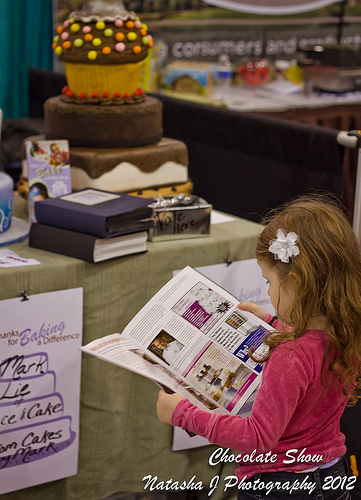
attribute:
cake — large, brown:
[28, 0, 214, 208]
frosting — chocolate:
[50, 5, 153, 60]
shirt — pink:
[168, 313, 356, 486]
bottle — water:
[217, 53, 230, 92]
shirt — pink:
[171, 326, 350, 467]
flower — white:
[263, 228, 302, 263]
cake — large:
[17, 0, 190, 208]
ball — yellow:
[87, 51, 103, 61]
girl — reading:
[195, 189, 357, 491]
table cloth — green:
[2, 186, 275, 497]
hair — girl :
[247, 187, 359, 405]